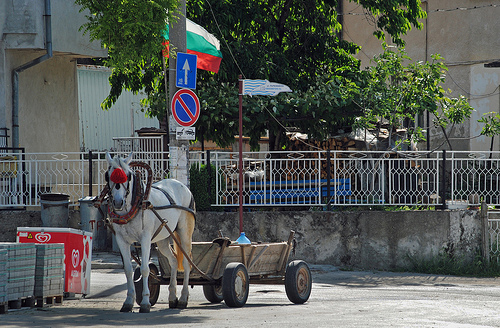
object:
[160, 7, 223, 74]
flag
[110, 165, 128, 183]
tassle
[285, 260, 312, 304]
wheel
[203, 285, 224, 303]
wheel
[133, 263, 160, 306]
wheel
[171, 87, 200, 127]
sign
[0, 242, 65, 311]
pallets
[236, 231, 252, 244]
blue bottle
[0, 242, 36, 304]
bricks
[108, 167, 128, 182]
flower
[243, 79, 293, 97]
flag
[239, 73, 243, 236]
pole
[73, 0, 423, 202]
tree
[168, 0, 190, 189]
pole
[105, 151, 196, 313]
horse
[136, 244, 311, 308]
trailer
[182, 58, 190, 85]
arrow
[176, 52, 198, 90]
blue sign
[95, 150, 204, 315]
bathroom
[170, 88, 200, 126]
circle line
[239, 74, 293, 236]
street sign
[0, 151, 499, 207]
fence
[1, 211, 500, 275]
wall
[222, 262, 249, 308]
wheels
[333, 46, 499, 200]
trees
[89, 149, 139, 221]
head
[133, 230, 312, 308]
wagon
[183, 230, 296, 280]
palates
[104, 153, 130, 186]
pom pom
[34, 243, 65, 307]
materials